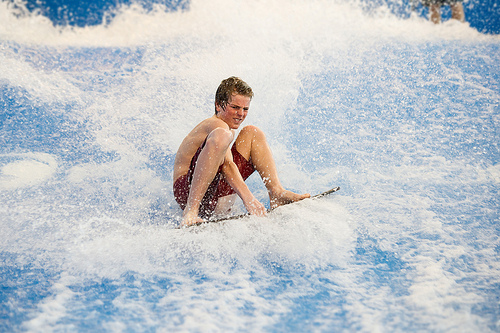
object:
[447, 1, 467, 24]
legs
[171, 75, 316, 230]
surfer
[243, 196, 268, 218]
hand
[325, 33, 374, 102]
big splashes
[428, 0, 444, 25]
legs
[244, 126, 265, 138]
knees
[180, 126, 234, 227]
leg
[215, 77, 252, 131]
head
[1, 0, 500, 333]
water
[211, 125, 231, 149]
knees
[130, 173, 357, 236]
surfboard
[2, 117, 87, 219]
swirl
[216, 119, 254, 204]
arm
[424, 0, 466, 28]
object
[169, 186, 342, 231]
board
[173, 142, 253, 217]
shorts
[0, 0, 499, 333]
ocean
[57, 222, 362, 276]
wave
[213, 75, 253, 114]
hair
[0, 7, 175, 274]
wave